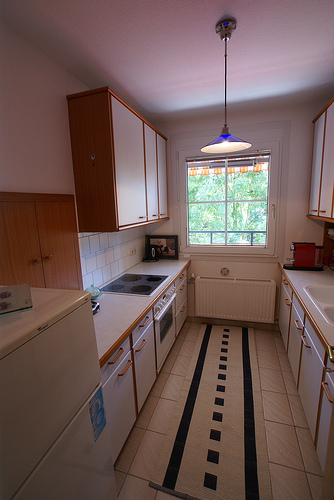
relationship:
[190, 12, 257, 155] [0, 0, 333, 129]
light hanging from ceiling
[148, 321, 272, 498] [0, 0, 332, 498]
rug in kitchen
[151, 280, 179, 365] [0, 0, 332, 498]
oven in kitchen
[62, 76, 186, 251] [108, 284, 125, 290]
cabinets above burner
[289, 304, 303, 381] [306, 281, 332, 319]
door under sink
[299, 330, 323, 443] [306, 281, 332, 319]
door under sink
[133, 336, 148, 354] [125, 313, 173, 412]
handle on cabinet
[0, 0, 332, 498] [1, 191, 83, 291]
kitchen has cabinet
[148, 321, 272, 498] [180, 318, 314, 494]
rug on floor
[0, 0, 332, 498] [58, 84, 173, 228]
kitchen has cabinets